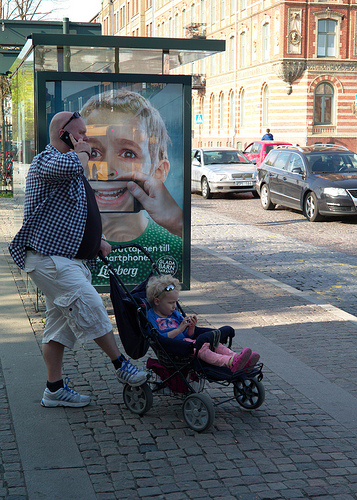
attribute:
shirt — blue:
[153, 314, 177, 327]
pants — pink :
[195, 339, 233, 367]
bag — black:
[108, 275, 153, 356]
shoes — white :
[34, 348, 152, 409]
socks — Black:
[35, 354, 135, 417]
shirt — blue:
[149, 310, 187, 337]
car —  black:
[257, 146, 356, 221]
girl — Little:
[117, 235, 272, 383]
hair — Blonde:
[141, 270, 184, 303]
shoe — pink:
[234, 348, 247, 368]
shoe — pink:
[247, 351, 261, 371]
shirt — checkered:
[9, 147, 88, 267]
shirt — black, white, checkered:
[1, 141, 89, 263]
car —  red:
[236, 139, 294, 171]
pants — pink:
[183, 335, 236, 365]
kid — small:
[144, 276, 260, 374]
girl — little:
[117, 266, 292, 403]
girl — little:
[139, 281, 261, 373]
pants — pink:
[179, 332, 256, 377]